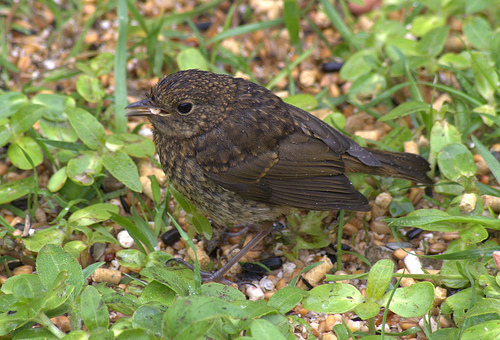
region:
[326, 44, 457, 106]
The leaf is great.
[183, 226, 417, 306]
The grass has lots of rocks in it.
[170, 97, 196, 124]
His eye is black.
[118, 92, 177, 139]
The beak is black.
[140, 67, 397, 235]
The bird is brown.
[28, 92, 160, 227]
The leaves are small.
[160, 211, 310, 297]
The birds legs are skinny.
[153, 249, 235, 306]
The bird's feet are long.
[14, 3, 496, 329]
The ground has grass and rocks.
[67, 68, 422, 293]
The bird is standing.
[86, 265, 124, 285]
Cylindrical bird seed on the ground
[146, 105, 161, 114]
Seed in a bird's mouth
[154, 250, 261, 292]
Bird's claw on the ground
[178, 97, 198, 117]
Black eye of a bird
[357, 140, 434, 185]
Bird's brown tail feathers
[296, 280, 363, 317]
Green leave on a plant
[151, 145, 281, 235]
Bird's breast feathers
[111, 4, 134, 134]
Green blade of grass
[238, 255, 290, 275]
Black sunflower seed on the ground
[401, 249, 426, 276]
White piece of bird food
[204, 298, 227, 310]
leaf of a plant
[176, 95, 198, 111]
eye of a bird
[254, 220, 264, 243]
leg of a bird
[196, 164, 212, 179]
feather of a bird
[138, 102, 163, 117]
beak of a bird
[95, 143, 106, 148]
tip of a plant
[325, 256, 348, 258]
part of a surface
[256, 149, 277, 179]
feather of a bird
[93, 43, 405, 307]
Bird on the ground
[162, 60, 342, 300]
Bird is black with tan spots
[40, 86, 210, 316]
Green leaves on ground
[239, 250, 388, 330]
Orange debris on ground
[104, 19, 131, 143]
Green blades of grass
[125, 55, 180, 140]
Bird has beak open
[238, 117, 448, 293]
Bird has a black tail feather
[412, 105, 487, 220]
Green leaves are wet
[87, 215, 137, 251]
White pebbles on ground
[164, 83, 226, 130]
Bird has black eye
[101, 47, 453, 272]
small brown bird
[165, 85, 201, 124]
black eye of small brown bird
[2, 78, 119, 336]
foliage on forest floor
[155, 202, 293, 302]
leg of small brown bird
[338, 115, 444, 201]
tail of small brown bird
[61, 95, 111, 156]
light green leaf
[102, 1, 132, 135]
green blade of grass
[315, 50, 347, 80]
small black stone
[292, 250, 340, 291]
small tan stone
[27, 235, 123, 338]
small light green leaves